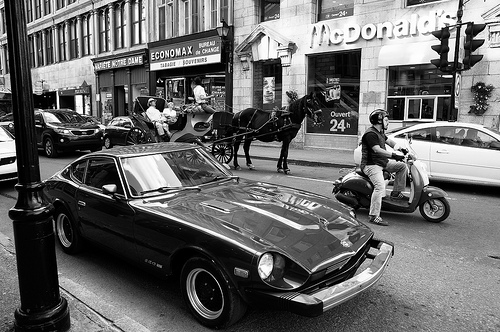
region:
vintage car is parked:
[31, 118, 391, 330]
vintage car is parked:
[44, 114, 395, 322]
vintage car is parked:
[42, 111, 386, 319]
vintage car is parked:
[44, 100, 399, 320]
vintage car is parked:
[34, 114, 394, 323]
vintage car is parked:
[40, 110, 397, 313]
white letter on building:
[330, 27, 343, 44]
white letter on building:
[343, 21, 361, 45]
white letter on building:
[361, 23, 376, 40]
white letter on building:
[376, 20, 393, 42]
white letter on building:
[393, 18, 409, 35]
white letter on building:
[408, 12, 418, 37]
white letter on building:
[416, 8, 436, 35]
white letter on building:
[186, 45, 193, 55]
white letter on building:
[179, 46, 188, 56]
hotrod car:
[35, 139, 395, 329]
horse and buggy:
[133, 84, 330, 166]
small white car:
[344, 116, 498, 198]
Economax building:
[147, 4, 230, 136]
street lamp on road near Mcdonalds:
[201, 18, 236, 143]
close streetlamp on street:
[1, 0, 71, 330]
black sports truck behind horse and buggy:
[5, 101, 107, 152]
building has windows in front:
[383, 67, 453, 127]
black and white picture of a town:
[42, 8, 499, 327]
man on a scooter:
[333, 98, 465, 238]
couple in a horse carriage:
[122, 43, 351, 172]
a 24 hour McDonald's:
[229, 4, 499, 212]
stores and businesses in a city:
[66, 6, 321, 188]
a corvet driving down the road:
[18, 120, 423, 317]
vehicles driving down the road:
[36, 75, 455, 305]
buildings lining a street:
[24, 2, 499, 224]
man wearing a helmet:
[343, 94, 470, 266]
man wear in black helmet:
[331, 108, 458, 225]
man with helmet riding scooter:
[332, 107, 449, 223]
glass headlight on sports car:
[254, 247, 292, 289]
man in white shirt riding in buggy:
[142, 97, 168, 137]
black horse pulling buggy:
[198, 94, 328, 170]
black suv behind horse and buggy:
[34, 104, 101, 156]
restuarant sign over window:
[304, 7, 463, 44]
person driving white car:
[463, 127, 488, 147]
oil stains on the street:
[394, 296, 418, 325]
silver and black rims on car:
[179, 259, 231, 328]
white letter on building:
[148, 51, 157, 61]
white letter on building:
[153, 49, 160, 60]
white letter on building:
[158, 50, 164, 59]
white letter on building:
[168, 47, 174, 57]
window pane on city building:
[131, 22, 139, 45]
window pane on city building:
[140, 19, 148, 43]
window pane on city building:
[388, 97, 406, 120]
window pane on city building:
[407, 97, 420, 119]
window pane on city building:
[435, 95, 452, 120]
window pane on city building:
[388, 64, 453, 95]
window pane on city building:
[307, 49, 362, 135]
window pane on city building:
[260, 58, 282, 109]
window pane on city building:
[81, 16, 88, 36]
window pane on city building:
[88, 12, 94, 35]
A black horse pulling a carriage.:
[229, 89, 324, 176]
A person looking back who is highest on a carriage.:
[191, 75, 216, 113]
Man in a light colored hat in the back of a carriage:
[145, 96, 173, 138]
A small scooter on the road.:
[333, 149, 450, 224]